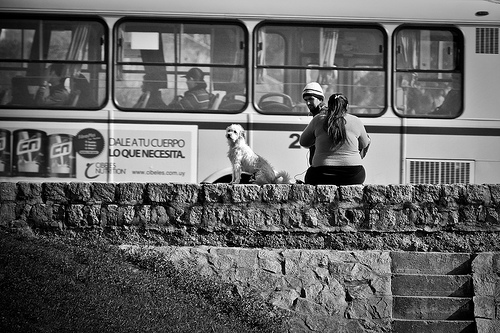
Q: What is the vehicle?
A: Bus.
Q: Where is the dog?
A: On the wall.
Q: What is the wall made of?
A: Stone.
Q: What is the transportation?
A: Bus.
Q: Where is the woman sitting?
A: On the wall.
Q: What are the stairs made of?
A: Stone.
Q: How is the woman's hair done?
A: Ponytail.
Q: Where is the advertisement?
A: On the bus.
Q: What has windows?
A: Bus.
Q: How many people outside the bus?
A: Two.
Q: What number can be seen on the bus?
A: 2.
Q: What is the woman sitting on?
A: A stone wall.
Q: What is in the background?
A: A bus.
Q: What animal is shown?
A: A dog.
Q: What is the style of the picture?
A: Black and white.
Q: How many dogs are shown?
A: One.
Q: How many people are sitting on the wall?
A: One.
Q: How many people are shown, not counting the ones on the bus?
A: Two.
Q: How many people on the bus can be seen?
A: Two.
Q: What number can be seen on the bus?
A: 2.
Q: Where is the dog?
A: On the wall.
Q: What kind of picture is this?
A: Black and white.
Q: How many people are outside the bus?
A: 2.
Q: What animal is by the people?
A: A dog.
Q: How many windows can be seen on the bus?
A: 4.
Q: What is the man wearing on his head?
A: A hat.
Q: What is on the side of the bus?
A: An advertisement.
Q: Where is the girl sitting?
A: On a wall.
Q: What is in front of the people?
A: A bus.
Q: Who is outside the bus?
A: A man and woman.